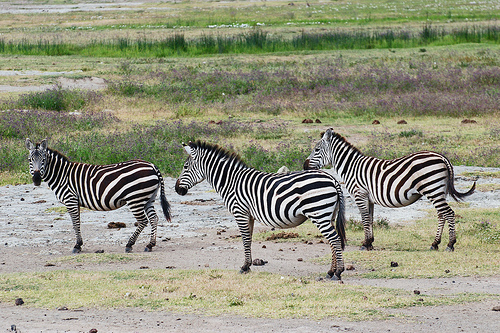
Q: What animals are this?
A: Zebra.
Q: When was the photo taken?
A: Daytime.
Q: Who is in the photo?
A: Nobody.